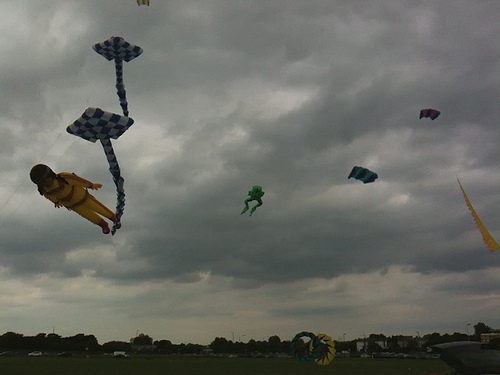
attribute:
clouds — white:
[111, 112, 479, 297]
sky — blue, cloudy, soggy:
[0, 2, 499, 322]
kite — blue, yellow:
[32, 61, 218, 257]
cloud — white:
[262, 289, 375, 316]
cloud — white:
[5, 219, 120, 289]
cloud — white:
[334, 10, 475, 94]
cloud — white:
[204, 28, 365, 163]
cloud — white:
[415, 183, 497, 271]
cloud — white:
[125, 68, 497, 286]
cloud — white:
[91, 3, 496, 81]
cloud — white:
[1, 191, 112, 282]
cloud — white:
[2, 1, 100, 128]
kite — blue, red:
[382, 99, 472, 151]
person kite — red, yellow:
[18, 153, 117, 235]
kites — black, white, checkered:
[28, 37, 175, 190]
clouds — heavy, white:
[0, 1, 497, 345]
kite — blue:
[309, 129, 394, 192]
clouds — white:
[154, 52, 328, 157]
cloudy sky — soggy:
[2, 2, 498, 340]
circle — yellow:
[308, 331, 336, 365]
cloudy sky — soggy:
[17, 17, 478, 347]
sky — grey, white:
[216, 15, 466, 254]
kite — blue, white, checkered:
[85, 60, 220, 244]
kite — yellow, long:
[446, 158, 498, 280]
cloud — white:
[239, 70, 330, 127]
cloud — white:
[122, 115, 193, 166]